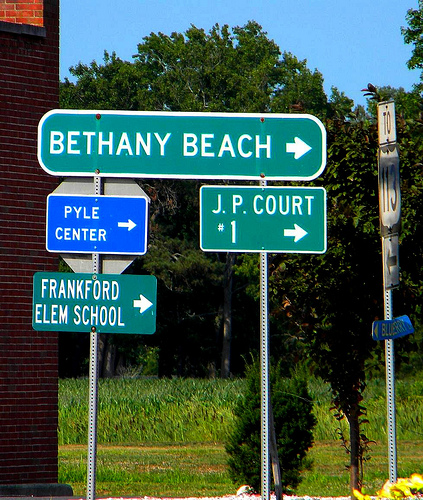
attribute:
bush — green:
[228, 350, 313, 497]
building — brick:
[0, 1, 74, 496]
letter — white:
[95, 128, 116, 157]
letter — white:
[61, 129, 87, 156]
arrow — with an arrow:
[116, 216, 138, 234]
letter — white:
[96, 132, 111, 156]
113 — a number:
[376, 160, 398, 215]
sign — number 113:
[366, 92, 404, 233]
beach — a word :
[183, 131, 271, 159]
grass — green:
[62, 447, 418, 492]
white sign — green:
[83, 86, 320, 178]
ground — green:
[371, 111, 386, 131]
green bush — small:
[225, 348, 319, 498]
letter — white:
[213, 131, 234, 164]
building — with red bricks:
[11, 41, 48, 83]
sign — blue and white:
[19, 100, 351, 188]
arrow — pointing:
[277, 126, 321, 167]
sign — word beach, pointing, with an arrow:
[37, 105, 326, 182]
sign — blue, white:
[43, 192, 148, 255]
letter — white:
[48, 128, 64, 154]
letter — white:
[151, 127, 173, 159]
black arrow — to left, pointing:
[381, 247, 400, 279]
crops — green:
[58, 376, 419, 448]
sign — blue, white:
[41, 185, 167, 262]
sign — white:
[22, 101, 289, 182]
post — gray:
[256, 252, 271, 498]